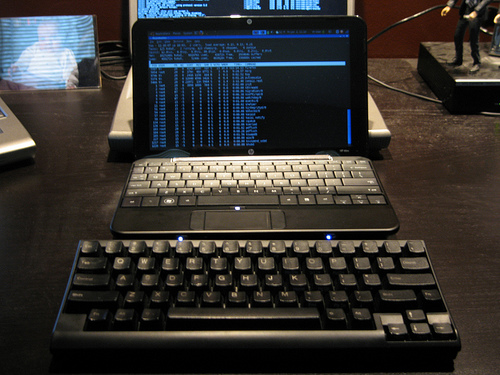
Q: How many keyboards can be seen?
A: Two.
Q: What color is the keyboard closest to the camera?
A: Black.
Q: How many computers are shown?
A: 2.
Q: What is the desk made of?
A: Wood.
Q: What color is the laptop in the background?
A: Silver.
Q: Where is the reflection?
A: On the Photo.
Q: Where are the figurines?
A: Top right.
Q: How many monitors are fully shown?
A: 1.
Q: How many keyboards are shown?
A: 2.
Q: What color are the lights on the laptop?
A: Blue.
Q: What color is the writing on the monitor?
A: Blue.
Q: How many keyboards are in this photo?
A: 2.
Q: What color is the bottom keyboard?
A: Black.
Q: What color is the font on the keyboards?
A: White.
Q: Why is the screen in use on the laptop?
A: Because someone used the keyboards.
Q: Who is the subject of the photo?
A: Th electronics.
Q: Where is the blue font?
A: On the computer screen.